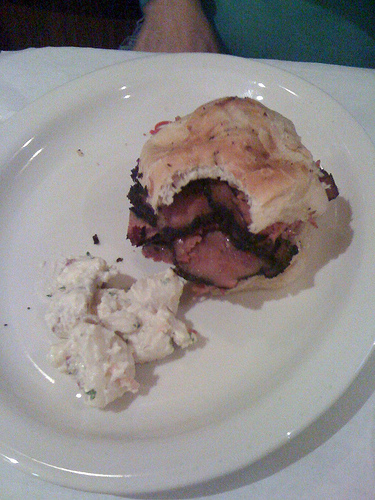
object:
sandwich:
[124, 93, 341, 300]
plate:
[0, 48, 375, 500]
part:
[86, 386, 98, 401]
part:
[189, 326, 197, 336]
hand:
[128, 0, 219, 52]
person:
[115, 2, 375, 71]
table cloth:
[0, 45, 375, 500]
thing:
[152, 121, 169, 131]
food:
[44, 249, 199, 407]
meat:
[171, 228, 270, 290]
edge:
[251, 444, 285, 458]